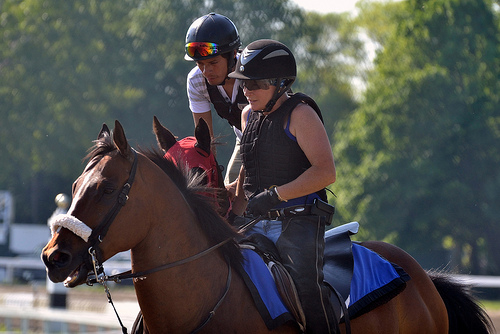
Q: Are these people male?
A: No, they are both male and female.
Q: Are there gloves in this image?
A: Yes, there are gloves.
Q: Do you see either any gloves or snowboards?
A: Yes, there are gloves.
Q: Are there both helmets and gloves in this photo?
A: Yes, there are both gloves and a helmet.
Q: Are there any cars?
A: No, there are no cars.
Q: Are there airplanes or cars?
A: No, there are no cars or airplanes.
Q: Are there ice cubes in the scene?
A: No, there are no ice cubes.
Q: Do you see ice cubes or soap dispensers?
A: No, there are no ice cubes or soap dispensers.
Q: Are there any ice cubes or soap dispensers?
A: No, there are no ice cubes or soap dispensers.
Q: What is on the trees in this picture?
A: The leaves are on the trees.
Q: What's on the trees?
A: The leaves are on the trees.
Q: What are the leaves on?
A: The leaves are on the trees.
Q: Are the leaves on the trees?
A: Yes, the leaves are on the trees.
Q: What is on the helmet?
A: The logo is on the helmet.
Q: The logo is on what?
A: The logo is on the helmet.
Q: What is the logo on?
A: The logo is on the helmet.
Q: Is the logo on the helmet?
A: Yes, the logo is on the helmet.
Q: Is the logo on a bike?
A: No, the logo is on the helmet.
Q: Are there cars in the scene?
A: No, there are no cars.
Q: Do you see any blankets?
A: Yes, there is a blanket.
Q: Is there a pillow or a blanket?
A: Yes, there is a blanket.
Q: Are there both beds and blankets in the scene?
A: No, there is a blanket but no beds.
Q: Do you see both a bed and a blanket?
A: No, there is a blanket but no beds.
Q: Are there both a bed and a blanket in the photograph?
A: No, there is a blanket but no beds.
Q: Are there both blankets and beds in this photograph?
A: No, there is a blanket but no beds.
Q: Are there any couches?
A: No, there are no couches.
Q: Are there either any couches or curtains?
A: No, there are no couches or curtains.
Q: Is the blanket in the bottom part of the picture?
A: Yes, the blanket is in the bottom of the image.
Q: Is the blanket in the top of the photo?
A: No, the blanket is in the bottom of the image.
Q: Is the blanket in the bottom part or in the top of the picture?
A: The blanket is in the bottom of the image.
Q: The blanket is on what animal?
A: The blanket is on the horse.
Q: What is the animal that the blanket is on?
A: The animal is a horse.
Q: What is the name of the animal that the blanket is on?
A: The animal is a horse.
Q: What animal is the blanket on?
A: The blanket is on the horse.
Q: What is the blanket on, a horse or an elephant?
A: The blanket is on a horse.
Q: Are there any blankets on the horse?
A: Yes, there is a blanket on the horse.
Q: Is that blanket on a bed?
A: No, the blanket is on the horse.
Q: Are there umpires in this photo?
A: No, there are no umpires.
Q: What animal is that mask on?
A: The mask is on the horse.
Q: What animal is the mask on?
A: The mask is on the horse.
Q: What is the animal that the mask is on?
A: The animal is a horse.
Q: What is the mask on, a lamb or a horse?
A: The mask is on a horse.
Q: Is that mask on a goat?
A: No, the mask is on a horse.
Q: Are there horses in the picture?
A: Yes, there is a horse.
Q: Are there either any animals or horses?
A: Yes, there is a horse.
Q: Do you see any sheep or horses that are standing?
A: Yes, the horse is standing.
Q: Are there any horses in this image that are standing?
A: Yes, there is a horse that is standing.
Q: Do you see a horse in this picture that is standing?
A: Yes, there is a horse that is standing.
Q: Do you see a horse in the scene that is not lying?
A: Yes, there is a horse that is standing .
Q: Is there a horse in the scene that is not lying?
A: Yes, there is a horse that is standing.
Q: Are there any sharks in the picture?
A: No, there are no sharks.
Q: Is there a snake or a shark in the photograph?
A: No, there are no sharks or snakes.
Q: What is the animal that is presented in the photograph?
A: The animal is a horse.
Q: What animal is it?
A: The animal is a horse.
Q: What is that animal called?
A: This is a horse.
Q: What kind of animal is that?
A: This is a horse.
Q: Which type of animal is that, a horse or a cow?
A: This is a horse.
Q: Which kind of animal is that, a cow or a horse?
A: This is a horse.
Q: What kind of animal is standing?
A: The animal is a horse.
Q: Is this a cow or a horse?
A: This is a horse.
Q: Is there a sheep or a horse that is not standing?
A: No, there is a horse but it is standing.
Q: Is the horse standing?
A: Yes, the horse is standing.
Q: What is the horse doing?
A: The horse is standing.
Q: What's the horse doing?
A: The horse is standing.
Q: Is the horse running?
A: No, the horse is standing.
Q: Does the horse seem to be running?
A: No, the horse is standing.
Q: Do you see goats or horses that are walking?
A: No, there is a horse but it is standing.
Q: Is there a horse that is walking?
A: No, there is a horse but it is standing.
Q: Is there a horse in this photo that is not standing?
A: No, there is a horse but it is standing.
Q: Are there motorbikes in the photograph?
A: No, there are no motorbikes.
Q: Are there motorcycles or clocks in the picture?
A: No, there are no motorcycles or clocks.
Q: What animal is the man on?
A: The man is on the horse.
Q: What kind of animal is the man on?
A: The man is on the horse.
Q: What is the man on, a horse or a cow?
A: The man is on a horse.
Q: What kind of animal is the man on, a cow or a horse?
A: The man is on a horse.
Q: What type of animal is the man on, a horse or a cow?
A: The man is on a horse.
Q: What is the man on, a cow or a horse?
A: The man is on a horse.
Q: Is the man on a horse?
A: Yes, the man is on a horse.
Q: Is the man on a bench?
A: No, the man is on a horse.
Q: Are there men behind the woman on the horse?
A: Yes, there is a man behind the woman.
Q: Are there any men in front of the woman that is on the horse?
A: No, the man is behind the woman.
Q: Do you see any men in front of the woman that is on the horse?
A: No, the man is behind the woman.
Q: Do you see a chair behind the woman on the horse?
A: No, there is a man behind the woman.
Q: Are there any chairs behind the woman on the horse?
A: No, there is a man behind the woman.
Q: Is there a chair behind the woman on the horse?
A: No, there is a man behind the woman.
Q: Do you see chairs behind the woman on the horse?
A: No, there is a man behind the woman.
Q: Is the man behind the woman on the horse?
A: Yes, the man is behind the woman.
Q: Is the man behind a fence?
A: No, the man is behind the woman.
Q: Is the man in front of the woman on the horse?
A: No, the man is behind the woman.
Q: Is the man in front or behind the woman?
A: The man is behind the woman.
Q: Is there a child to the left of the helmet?
A: No, there is a man to the left of the helmet.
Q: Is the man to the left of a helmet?
A: Yes, the man is to the left of a helmet.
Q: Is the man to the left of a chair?
A: No, the man is to the left of a helmet.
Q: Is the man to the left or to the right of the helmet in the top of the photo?
A: The man is to the left of the helmet.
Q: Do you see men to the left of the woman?
A: Yes, there is a man to the left of the woman.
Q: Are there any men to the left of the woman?
A: Yes, there is a man to the left of the woman.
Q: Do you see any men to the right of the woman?
A: No, the man is to the left of the woman.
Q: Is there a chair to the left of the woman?
A: No, there is a man to the left of the woman.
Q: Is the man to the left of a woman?
A: Yes, the man is to the left of a woman.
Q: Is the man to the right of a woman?
A: No, the man is to the left of a woman.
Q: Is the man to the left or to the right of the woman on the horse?
A: The man is to the left of the woman.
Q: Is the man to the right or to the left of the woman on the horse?
A: The man is to the left of the woman.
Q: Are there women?
A: Yes, there is a woman.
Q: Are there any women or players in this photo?
A: Yes, there is a woman.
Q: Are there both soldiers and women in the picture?
A: No, there is a woman but no soldiers.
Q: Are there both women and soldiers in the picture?
A: No, there is a woman but no soldiers.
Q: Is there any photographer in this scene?
A: No, there are no photographers.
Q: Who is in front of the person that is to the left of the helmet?
A: The woman is in front of the man.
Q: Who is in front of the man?
A: The woman is in front of the man.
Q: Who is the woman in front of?
A: The woman is in front of the man.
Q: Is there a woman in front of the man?
A: Yes, there is a woman in front of the man.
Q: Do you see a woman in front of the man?
A: Yes, there is a woman in front of the man.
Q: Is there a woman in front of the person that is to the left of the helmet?
A: Yes, there is a woman in front of the man.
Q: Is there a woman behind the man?
A: No, the woman is in front of the man.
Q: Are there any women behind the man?
A: No, the woman is in front of the man.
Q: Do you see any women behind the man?
A: No, the woman is in front of the man.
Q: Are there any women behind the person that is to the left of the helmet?
A: No, the woman is in front of the man.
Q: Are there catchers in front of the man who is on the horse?
A: No, there is a woman in front of the man.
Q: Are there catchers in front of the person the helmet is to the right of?
A: No, there is a woman in front of the man.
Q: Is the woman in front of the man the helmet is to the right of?
A: Yes, the woman is in front of the man.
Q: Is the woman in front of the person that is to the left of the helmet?
A: Yes, the woman is in front of the man.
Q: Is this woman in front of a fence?
A: No, the woman is in front of the man.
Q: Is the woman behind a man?
A: No, the woman is in front of a man.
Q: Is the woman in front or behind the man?
A: The woman is in front of the man.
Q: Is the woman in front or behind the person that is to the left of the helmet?
A: The woman is in front of the man.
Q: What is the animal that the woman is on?
A: The animal is a horse.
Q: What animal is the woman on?
A: The woman is on the horse.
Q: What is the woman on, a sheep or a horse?
A: The woman is on a horse.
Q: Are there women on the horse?
A: Yes, there is a woman on the horse.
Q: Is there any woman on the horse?
A: Yes, there is a woman on the horse.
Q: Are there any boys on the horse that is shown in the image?
A: No, there is a woman on the horse.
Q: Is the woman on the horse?
A: Yes, the woman is on the horse.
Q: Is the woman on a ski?
A: No, the woman is on the horse.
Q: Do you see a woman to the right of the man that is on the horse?
A: Yes, there is a woman to the right of the man.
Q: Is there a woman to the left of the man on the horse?
A: No, the woman is to the right of the man.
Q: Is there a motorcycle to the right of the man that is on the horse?
A: No, there is a woman to the right of the man.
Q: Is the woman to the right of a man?
A: Yes, the woman is to the right of a man.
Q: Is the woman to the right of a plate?
A: No, the woman is to the right of a man.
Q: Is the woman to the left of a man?
A: No, the woman is to the right of a man.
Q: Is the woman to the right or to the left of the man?
A: The woman is to the right of the man.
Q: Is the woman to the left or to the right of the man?
A: The woman is to the right of the man.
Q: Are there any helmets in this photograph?
A: Yes, there is a helmet.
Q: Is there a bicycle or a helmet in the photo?
A: Yes, there is a helmet.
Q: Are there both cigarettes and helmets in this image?
A: No, there is a helmet but no cigarettes.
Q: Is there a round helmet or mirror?
A: Yes, there is a round helmet.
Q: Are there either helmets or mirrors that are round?
A: Yes, the helmet is round.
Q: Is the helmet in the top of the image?
A: Yes, the helmet is in the top of the image.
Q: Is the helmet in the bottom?
A: No, the helmet is in the top of the image.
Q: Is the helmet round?
A: Yes, the helmet is round.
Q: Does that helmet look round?
A: Yes, the helmet is round.